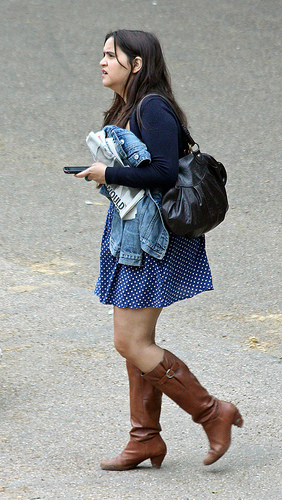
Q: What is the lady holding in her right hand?
A: Mobile phone.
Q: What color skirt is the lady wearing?
A: Blue.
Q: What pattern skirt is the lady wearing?
A: Polka Dots.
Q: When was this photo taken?
A: Daytime.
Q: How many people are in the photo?
A: One.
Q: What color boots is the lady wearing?
A: Brown.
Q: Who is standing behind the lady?
A: No one.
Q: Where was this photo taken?
A: On a street.